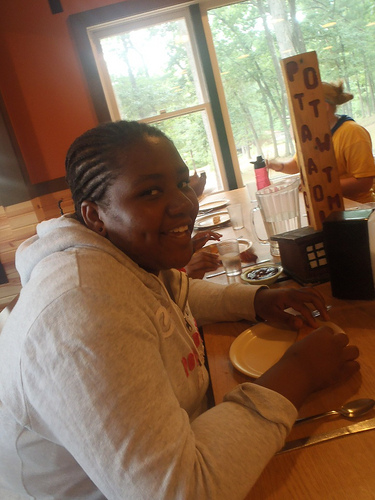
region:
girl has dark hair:
[41, 129, 171, 222]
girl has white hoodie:
[17, 240, 191, 461]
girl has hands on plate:
[231, 317, 314, 375]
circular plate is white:
[242, 316, 311, 378]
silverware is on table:
[293, 385, 365, 473]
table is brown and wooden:
[256, 353, 348, 460]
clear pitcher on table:
[247, 176, 301, 251]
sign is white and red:
[256, 41, 356, 259]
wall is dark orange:
[23, 54, 93, 148]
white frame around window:
[88, 37, 262, 240]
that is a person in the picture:
[3, 116, 321, 499]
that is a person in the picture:
[263, 81, 373, 200]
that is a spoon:
[288, 398, 372, 425]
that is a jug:
[253, 173, 304, 245]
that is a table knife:
[293, 413, 374, 463]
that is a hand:
[253, 287, 328, 328]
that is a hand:
[294, 316, 362, 394]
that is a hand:
[180, 246, 225, 274]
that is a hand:
[188, 223, 222, 247]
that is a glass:
[215, 219, 240, 284]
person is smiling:
[0, 113, 356, 498]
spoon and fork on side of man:
[286, 391, 373, 455]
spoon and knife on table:
[289, 390, 372, 464]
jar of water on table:
[241, 169, 310, 264]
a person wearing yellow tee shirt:
[243, 143, 373, 195]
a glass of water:
[212, 234, 246, 277]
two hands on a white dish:
[222, 273, 363, 412]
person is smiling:
[42, 111, 233, 318]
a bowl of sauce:
[235, 257, 286, 290]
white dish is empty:
[224, 311, 361, 411]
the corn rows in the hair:
[61, 122, 121, 199]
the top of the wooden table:
[268, 454, 369, 497]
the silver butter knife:
[283, 418, 373, 461]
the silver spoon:
[290, 386, 373, 430]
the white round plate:
[223, 306, 352, 376]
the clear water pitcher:
[233, 170, 311, 267]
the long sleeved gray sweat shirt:
[4, 211, 296, 497]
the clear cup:
[218, 235, 243, 276]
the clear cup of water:
[215, 234, 241, 281]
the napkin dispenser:
[320, 198, 374, 302]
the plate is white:
[227, 307, 371, 432]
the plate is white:
[225, 303, 275, 368]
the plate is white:
[210, 259, 321, 474]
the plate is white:
[234, 287, 339, 381]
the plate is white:
[270, 315, 332, 375]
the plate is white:
[251, 229, 304, 313]